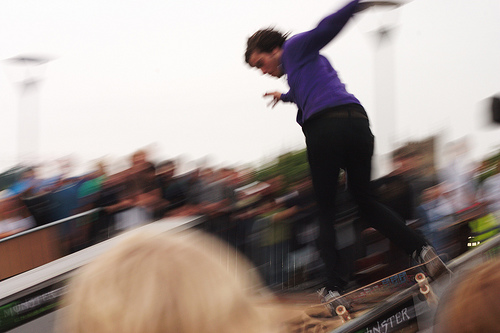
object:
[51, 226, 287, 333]
person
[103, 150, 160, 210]
person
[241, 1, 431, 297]
skateboarder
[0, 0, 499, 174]
sky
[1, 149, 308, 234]
background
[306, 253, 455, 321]
skateboard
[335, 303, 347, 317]
wheel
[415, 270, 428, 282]
wheel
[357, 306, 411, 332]
logo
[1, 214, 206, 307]
handrail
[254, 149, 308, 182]
trees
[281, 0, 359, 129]
shirt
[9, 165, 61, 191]
person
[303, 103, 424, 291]
jeans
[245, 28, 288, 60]
hair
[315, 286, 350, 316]
sneaker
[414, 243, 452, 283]
sneaker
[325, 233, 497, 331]
rail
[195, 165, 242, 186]
person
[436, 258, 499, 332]
head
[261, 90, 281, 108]
hand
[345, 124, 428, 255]
leg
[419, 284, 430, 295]
wheel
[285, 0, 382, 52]
arm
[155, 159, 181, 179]
person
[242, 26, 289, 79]
head